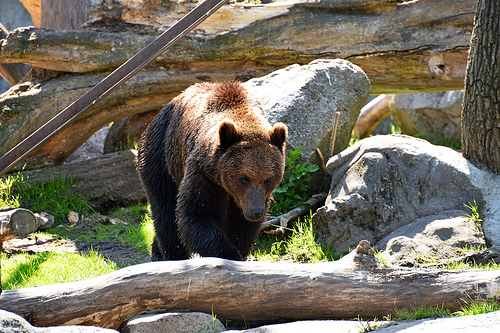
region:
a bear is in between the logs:
[113, 71, 305, 273]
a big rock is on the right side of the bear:
[320, 138, 499, 275]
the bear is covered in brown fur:
[120, 65, 297, 261]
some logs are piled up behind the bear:
[9, 3, 472, 154]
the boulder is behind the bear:
[231, 42, 339, 172]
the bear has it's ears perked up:
[218, 110, 295, 149]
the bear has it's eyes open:
[233, 170, 274, 190]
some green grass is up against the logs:
[8, 166, 85, 224]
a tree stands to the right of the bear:
[466, 3, 498, 170]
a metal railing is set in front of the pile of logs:
[12, 1, 260, 174]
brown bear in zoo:
[143, 81, 289, 287]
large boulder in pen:
[245, 41, 355, 186]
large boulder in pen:
[312, 154, 479, 269]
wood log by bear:
[17, 244, 430, 320]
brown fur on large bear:
[149, 98, 201, 151]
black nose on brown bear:
[243, 194, 264, 229]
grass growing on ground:
[280, 212, 305, 244]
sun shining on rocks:
[378, 209, 447, 262]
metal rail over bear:
[57, 17, 127, 119]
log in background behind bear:
[27, 28, 412, 118]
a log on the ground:
[53, 279, 125, 329]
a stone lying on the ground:
[343, 139, 453, 217]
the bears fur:
[176, 88, 233, 134]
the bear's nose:
[245, 203, 273, 223]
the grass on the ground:
[10, 246, 111, 280]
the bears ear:
[215, 120, 251, 142]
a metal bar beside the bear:
[31, 119, 63, 141]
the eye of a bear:
[234, 172, 259, 188]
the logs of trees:
[356, 10, 464, 94]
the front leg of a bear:
[176, 185, 242, 266]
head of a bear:
[212, 111, 300, 221]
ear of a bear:
[220, 119, 245, 137]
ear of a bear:
[267, 116, 294, 154]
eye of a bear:
[233, 156, 268, 180]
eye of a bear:
[253, 166, 291, 197]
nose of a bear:
[246, 198, 270, 212]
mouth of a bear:
[232, 199, 297, 229]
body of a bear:
[122, 51, 269, 186]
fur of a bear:
[173, 119, 225, 143]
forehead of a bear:
[229, 148, 273, 173]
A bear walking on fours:
[137, 107, 285, 257]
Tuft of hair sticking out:
[219, 82, 240, 101]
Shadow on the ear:
[220, 127, 235, 141]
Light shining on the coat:
[187, 94, 202, 111]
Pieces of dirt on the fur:
[195, 190, 210, 208]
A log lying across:
[222, 278, 350, 310]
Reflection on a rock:
[269, 80, 291, 105]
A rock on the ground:
[382, 182, 462, 249]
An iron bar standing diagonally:
[45, 125, 55, 132]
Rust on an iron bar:
[70, 107, 78, 114]